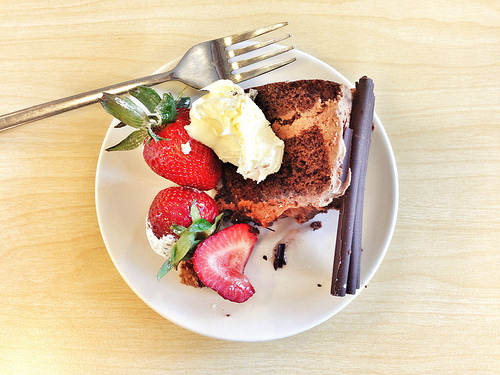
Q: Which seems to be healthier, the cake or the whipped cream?
A: The cake is healthier than the whipped cream.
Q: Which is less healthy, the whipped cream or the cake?
A: The whipped cream is less healthy than the cake.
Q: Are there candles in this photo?
A: No, there are no candles.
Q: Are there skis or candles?
A: No, there are no candles or skis.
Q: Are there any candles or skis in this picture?
A: No, there are no candles or skis.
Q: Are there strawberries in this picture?
A: Yes, there are strawberries.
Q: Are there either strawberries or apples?
A: Yes, there are strawberries.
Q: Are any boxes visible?
A: No, there are no boxes.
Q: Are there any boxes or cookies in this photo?
A: No, there are no boxes or cookies.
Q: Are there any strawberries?
A: Yes, there is a strawberry.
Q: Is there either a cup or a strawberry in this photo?
A: Yes, there is a strawberry.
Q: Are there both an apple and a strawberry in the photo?
A: No, there is a strawberry but no apples.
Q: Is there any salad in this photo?
A: No, there is no salad.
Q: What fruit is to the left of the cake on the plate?
A: The fruit is a strawberry.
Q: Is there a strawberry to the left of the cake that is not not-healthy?
A: Yes, there is a strawberry to the left of the cake.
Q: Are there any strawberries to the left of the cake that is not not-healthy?
A: Yes, there is a strawberry to the left of the cake.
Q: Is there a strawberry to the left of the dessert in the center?
A: Yes, there is a strawberry to the left of the cake.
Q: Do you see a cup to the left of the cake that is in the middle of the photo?
A: No, there is a strawberry to the left of the cake.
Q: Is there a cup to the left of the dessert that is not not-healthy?
A: No, there is a strawberry to the left of the cake.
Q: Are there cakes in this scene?
A: Yes, there is a cake.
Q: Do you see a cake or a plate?
A: Yes, there is a cake.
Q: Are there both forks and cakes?
A: Yes, there are both a cake and a fork.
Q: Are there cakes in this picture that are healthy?
A: Yes, there is a healthy cake.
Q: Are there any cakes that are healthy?
A: Yes, there is a cake that is healthy.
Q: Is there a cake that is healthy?
A: Yes, there is a cake that is healthy.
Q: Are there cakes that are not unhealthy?
A: Yes, there is an healthy cake.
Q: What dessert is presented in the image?
A: The dessert is a cake.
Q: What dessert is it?
A: The dessert is a cake.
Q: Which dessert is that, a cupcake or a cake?
A: That is a cake.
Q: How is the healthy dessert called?
A: The dessert is a cake.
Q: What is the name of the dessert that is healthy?
A: The dessert is a cake.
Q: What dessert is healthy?
A: The dessert is a cake.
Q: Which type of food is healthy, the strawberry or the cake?
A: The cake is healthy.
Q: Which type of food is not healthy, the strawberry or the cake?
A: The strawberry is not healthy.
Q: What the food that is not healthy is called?
A: The food is a strawberry.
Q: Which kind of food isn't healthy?
A: The food is a strawberry.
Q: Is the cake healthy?
A: Yes, the cake is healthy.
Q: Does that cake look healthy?
A: Yes, the cake is healthy.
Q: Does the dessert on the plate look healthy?
A: Yes, the cake is healthy.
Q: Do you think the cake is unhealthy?
A: No, the cake is healthy.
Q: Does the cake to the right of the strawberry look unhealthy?
A: No, the cake is healthy.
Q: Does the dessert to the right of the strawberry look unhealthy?
A: No, the cake is healthy.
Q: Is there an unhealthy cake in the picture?
A: No, there is a cake but it is healthy.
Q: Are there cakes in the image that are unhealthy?
A: No, there is a cake but it is healthy.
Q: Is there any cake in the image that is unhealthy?
A: No, there is a cake but it is healthy.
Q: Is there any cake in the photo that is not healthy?
A: No, there is a cake but it is healthy.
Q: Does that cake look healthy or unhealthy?
A: The cake is healthy.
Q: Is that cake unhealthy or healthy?
A: The cake is healthy.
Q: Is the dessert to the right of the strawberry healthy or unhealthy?
A: The cake is healthy.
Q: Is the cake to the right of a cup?
A: No, the cake is to the right of the strawberry.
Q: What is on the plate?
A: The cake is on the plate.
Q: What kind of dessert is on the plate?
A: The dessert is a cake.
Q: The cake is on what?
A: The cake is on the plate.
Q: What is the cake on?
A: The cake is on the plate.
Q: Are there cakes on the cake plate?
A: Yes, there is a cake on the plate.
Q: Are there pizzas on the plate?
A: No, there is a cake on the plate.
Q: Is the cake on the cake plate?
A: Yes, the cake is on the plate.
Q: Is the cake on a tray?
A: No, the cake is on the plate.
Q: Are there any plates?
A: Yes, there is a plate.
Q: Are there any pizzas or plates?
A: Yes, there is a plate.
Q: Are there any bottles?
A: No, there are no bottles.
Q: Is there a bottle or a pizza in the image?
A: No, there are no bottles or pizzas.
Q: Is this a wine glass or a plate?
A: This is a plate.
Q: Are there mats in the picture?
A: No, there are no mats.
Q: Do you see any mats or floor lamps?
A: No, there are no mats or floor lamps.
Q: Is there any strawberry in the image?
A: Yes, there is a strawberry.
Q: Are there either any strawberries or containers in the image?
A: Yes, there is a strawberry.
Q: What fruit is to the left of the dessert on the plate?
A: The fruit is a strawberry.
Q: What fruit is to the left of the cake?
A: The fruit is a strawberry.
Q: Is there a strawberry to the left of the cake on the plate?
A: Yes, there is a strawberry to the left of the cake.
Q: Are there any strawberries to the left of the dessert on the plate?
A: Yes, there is a strawberry to the left of the cake.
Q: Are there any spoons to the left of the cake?
A: No, there is a strawberry to the left of the cake.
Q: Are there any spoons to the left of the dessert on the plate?
A: No, there is a strawberry to the left of the cake.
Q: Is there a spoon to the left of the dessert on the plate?
A: No, there is a strawberry to the left of the cake.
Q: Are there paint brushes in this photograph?
A: No, there are no paint brushes.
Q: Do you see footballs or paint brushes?
A: No, there are no paint brushes or footballs.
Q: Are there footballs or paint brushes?
A: No, there are no paint brushes or footballs.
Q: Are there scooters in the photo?
A: No, there are no scooters.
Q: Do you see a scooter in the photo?
A: No, there are no scooters.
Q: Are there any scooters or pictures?
A: No, there are no scooters or pictures.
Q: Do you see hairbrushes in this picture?
A: No, there are no hairbrushes.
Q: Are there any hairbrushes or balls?
A: No, there are no hairbrushes or balls.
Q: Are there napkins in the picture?
A: No, there are no napkins.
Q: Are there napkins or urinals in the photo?
A: No, there are no napkins or urinals.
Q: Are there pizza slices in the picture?
A: No, there are no pizza slices.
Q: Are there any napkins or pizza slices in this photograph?
A: No, there are no pizza slices or napkins.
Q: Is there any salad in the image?
A: No, there is no salad.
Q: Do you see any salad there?
A: No, there is no salad.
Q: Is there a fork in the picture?
A: Yes, there is a fork.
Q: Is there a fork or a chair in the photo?
A: Yes, there is a fork.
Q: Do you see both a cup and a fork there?
A: No, there is a fork but no cups.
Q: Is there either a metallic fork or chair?
A: Yes, there is a metal fork.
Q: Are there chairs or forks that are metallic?
A: Yes, the fork is metallic.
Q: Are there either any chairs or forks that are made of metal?
A: Yes, the fork is made of metal.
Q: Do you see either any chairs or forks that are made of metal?
A: Yes, the fork is made of metal.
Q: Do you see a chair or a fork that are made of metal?
A: Yes, the fork is made of metal.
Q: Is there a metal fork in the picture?
A: Yes, there is a fork that is made of metal.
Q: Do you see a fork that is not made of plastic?
A: Yes, there is a fork that is made of metal.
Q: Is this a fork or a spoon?
A: This is a fork.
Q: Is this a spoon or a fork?
A: This is a fork.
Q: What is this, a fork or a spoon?
A: This is a fork.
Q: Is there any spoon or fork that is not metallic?
A: No, there is a fork but it is metallic.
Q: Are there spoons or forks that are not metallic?
A: No, there is a fork but it is metallic.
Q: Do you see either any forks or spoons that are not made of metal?
A: No, there is a fork but it is made of metal.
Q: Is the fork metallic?
A: Yes, the fork is metallic.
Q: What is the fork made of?
A: The fork is made of metal.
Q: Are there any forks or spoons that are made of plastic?
A: No, there is a fork but it is made of metal.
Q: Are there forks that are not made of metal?
A: No, there is a fork but it is made of metal.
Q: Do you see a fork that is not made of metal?
A: No, there is a fork but it is made of metal.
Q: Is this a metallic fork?
A: Yes, this is a metallic fork.